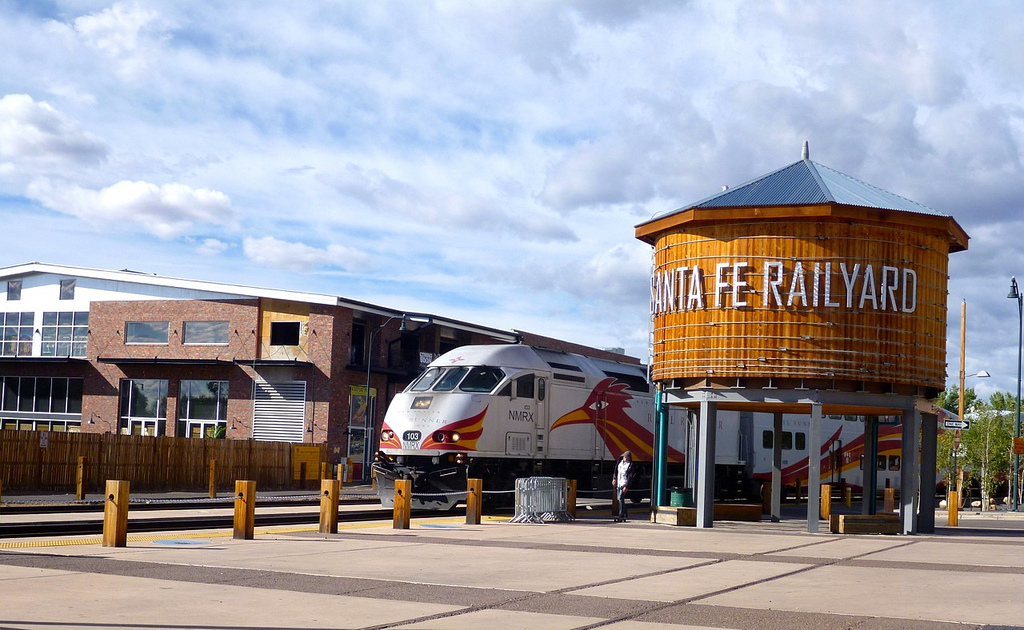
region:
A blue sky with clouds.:
[215, 221, 487, 314]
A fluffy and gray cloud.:
[544, 72, 723, 209]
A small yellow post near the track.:
[103, 475, 132, 545]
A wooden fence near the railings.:
[0, 427, 292, 491]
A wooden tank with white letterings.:
[631, 137, 973, 395]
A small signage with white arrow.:
[940, 417, 975, 428]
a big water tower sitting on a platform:
[635, 142, 953, 532]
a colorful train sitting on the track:
[376, 337, 902, 505]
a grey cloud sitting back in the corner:
[856, 110, 1022, 231]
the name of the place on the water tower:
[640, 262, 920, 316]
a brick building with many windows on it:
[79, 300, 390, 465]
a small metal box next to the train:
[509, 474, 574, 520]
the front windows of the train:
[408, 361, 497, 396]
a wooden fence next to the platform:
[10, 426, 331, 494]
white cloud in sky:
[27, 177, 249, 241]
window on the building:
[175, 318, 246, 353]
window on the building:
[104, 312, 180, 352]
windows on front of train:
[410, 361, 506, 399]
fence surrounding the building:
[6, 433, 84, 501]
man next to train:
[608, 452, 643, 516]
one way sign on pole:
[941, 414, 980, 437]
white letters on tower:
[758, 258, 930, 317]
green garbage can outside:
[668, 480, 697, 522]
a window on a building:
[3, 278, 30, 297]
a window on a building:
[54, 265, 78, 292]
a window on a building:
[105, 294, 181, 340]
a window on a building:
[256, 329, 320, 349]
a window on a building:
[130, 373, 156, 402]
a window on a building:
[189, 379, 228, 408]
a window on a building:
[35, 367, 61, 416]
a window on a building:
[19, 374, 33, 420]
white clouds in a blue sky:
[144, 63, 619, 234]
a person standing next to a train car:
[595, 440, 638, 524]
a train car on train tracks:
[374, 330, 924, 523]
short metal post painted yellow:
[89, 471, 481, 529]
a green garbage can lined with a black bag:
[661, 472, 701, 524]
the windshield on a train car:
[412, 358, 505, 393]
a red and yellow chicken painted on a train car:
[537, 357, 675, 469]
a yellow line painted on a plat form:
[152, 520, 399, 549]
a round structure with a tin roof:
[627, 128, 959, 392]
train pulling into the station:
[391, 335, 649, 500]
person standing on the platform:
[604, 432, 643, 518]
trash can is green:
[672, 478, 699, 516]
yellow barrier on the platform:
[89, 468, 137, 551]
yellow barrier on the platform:
[231, 476, 257, 535]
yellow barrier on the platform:
[312, 474, 342, 533]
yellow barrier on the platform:
[388, 468, 412, 529]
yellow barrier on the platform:
[458, 470, 498, 532]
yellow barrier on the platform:
[196, 452, 225, 498]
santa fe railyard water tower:
[618, 149, 992, 549]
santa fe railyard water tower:
[623, 152, 974, 536]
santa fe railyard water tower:
[621, 152, 982, 536]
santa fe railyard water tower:
[612, 149, 971, 543]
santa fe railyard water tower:
[618, 152, 974, 542]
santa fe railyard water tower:
[623, 161, 977, 541]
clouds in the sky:
[413, 101, 543, 234]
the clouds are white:
[427, 136, 557, 272]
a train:
[370, 335, 539, 466]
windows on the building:
[38, 314, 81, 352]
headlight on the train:
[442, 427, 465, 446]